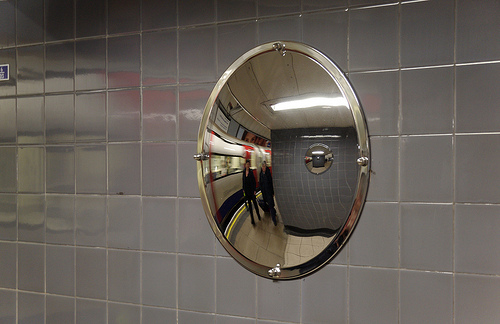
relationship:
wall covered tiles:
[34, 70, 137, 148] [404, 135, 472, 203]